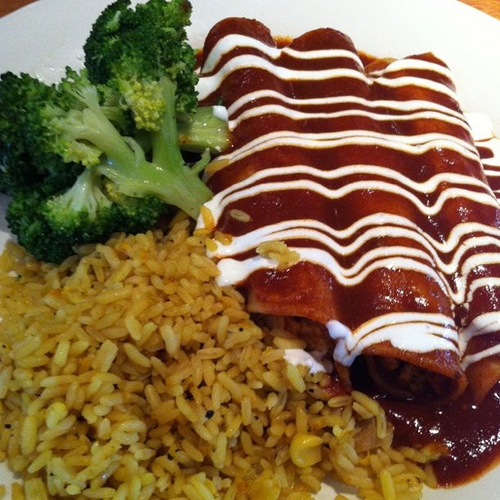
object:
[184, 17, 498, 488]
mexican food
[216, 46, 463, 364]
tamales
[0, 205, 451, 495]
rice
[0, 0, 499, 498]
food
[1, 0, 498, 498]
plate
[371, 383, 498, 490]
red sauce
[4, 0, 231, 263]
broccoli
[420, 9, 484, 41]
plate